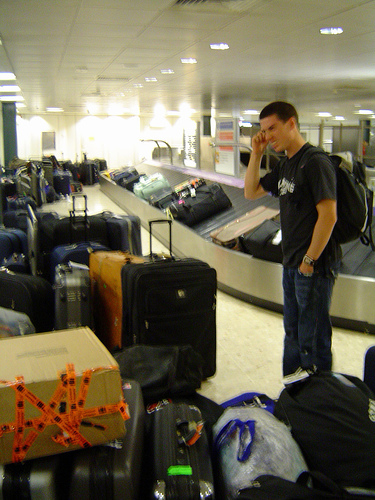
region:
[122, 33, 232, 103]
lights on ceiling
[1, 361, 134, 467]
orange tape on box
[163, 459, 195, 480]
green tag on suitcase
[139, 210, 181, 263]
handle on suitcase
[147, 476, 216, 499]
metal tips on edge of suitcase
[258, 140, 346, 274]
black short sleeve shirt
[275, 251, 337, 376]
pair of blue jeans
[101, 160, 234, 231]
line of suitcases on revolving belt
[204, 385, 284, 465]
blue handles on bag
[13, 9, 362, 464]
young man at baggage claim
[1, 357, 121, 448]
orange tape wrapped around a cardboard box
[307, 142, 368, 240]
man's back pack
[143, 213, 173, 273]
bag with handle extended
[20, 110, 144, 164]
windows to outside baggage claim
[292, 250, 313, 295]
wrist watch and left hand in pocket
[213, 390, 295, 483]
duffel bag with blue strap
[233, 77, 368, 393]
this is a man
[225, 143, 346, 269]
man wearing a black shirt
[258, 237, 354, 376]
man wearing blue jeans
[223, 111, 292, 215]
man has arm up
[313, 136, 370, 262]
man wearing a backpack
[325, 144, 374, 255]
the backpack is black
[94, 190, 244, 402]
this is a suitcase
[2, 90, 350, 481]
man looking at a field of luggage